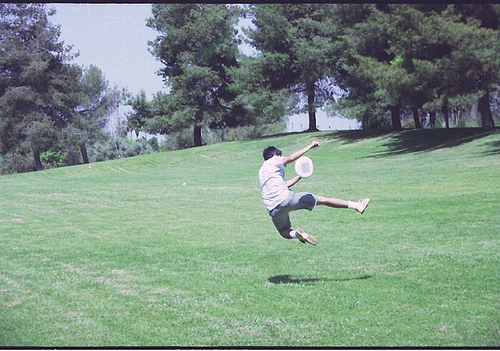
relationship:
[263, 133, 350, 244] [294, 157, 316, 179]
boy with frisbee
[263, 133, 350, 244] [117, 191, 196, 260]
boy on grass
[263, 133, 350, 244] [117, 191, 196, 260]
boy in grass